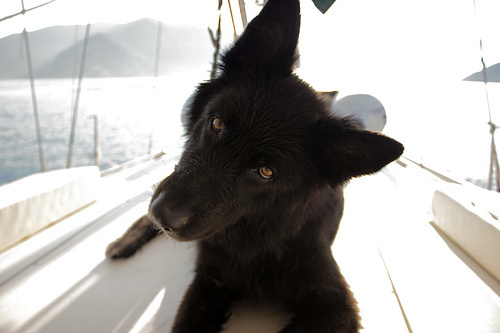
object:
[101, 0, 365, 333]
dog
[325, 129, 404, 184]
ears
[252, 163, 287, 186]
eyes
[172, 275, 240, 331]
legs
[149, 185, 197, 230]
nose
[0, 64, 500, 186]
water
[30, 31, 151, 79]
mountains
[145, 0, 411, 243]
head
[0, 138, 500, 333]
boat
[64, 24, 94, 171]
pole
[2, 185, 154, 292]
shadow